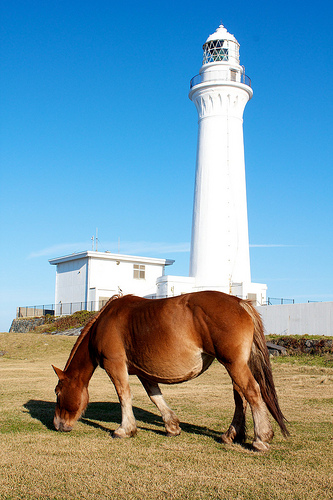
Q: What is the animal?
A: A horse.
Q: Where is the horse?
A: It is outside.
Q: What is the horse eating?
A: Eating grass.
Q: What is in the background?
A: A lighthouse.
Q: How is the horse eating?
A: With its mouth.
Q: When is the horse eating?
A: During the day.